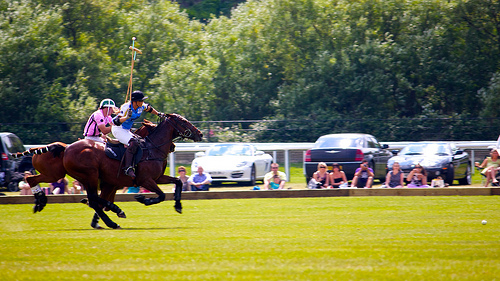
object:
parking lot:
[0, 159, 500, 196]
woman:
[474, 150, 499, 188]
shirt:
[480, 157, 499, 176]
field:
[343, 194, 499, 279]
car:
[190, 134, 472, 186]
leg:
[141, 180, 165, 204]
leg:
[157, 175, 183, 203]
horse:
[8, 113, 203, 230]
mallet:
[125, 36, 143, 103]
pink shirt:
[82, 110, 112, 137]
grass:
[0, 194, 500, 281]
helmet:
[131, 90, 149, 101]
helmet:
[100, 98, 116, 108]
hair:
[49, 144, 65, 158]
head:
[100, 98, 115, 116]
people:
[18, 147, 500, 195]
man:
[83, 91, 167, 178]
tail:
[8, 143, 66, 158]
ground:
[0, 163, 497, 281]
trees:
[0, 2, 500, 141]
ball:
[481, 220, 487, 225]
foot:
[123, 165, 137, 177]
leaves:
[278, 72, 445, 112]